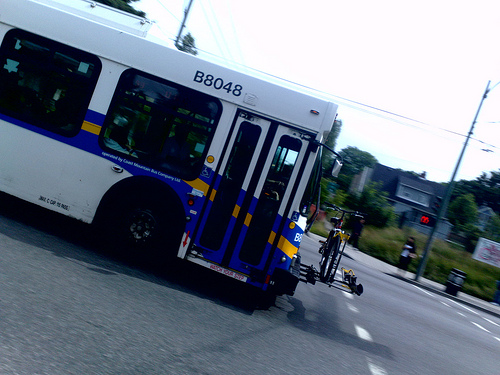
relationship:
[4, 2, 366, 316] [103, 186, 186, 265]
bus has tire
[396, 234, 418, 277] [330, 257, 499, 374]
pedestrian waiting to cross street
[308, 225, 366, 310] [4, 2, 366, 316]
rack on front of bus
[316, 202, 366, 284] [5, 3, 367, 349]
bicycle front of bus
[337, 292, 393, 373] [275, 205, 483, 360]
lines on pavement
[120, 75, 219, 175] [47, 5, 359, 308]
window at front of bus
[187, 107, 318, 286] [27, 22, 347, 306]
door on bus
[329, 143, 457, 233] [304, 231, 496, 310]
buildings behind sidewalk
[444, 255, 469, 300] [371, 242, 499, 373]
box on crosswalk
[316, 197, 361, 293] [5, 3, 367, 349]
bicycle on front of bus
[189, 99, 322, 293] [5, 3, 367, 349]
door on bus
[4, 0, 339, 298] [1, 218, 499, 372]
bus on street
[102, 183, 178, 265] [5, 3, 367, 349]
wheel on bus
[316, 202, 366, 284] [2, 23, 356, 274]
bicycle on bus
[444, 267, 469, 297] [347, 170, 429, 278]
box near corner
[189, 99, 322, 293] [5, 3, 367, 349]
door of bus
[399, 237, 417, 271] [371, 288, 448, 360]
pedestrian waiting to cross street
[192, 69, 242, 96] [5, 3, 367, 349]
id number of bus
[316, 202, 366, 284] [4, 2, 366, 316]
bicycle in front of bus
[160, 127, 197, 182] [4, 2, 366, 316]
person inside bus